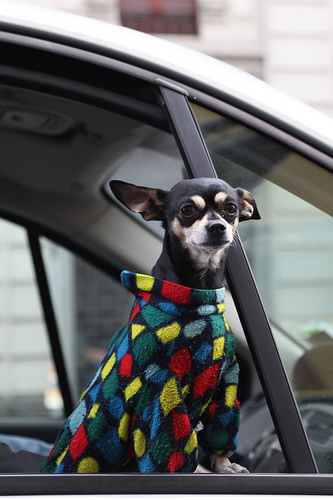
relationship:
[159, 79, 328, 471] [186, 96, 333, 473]
trim on window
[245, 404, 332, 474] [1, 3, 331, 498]
panel in car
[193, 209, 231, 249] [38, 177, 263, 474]
snout on dog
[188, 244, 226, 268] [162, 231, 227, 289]
patch on neck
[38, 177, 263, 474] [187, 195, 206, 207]
dog has eye brow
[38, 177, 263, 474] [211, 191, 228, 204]
dog has eye brow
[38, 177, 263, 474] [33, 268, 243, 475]
dog wearing jacket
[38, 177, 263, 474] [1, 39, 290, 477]
dog in window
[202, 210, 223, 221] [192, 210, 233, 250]
center of nose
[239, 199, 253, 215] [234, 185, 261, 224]
inside of ear